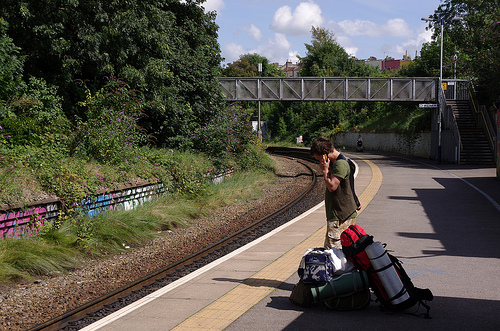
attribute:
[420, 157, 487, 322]
walkway — gray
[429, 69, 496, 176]
stairs — metal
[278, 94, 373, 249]
man — talking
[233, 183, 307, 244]
track — railroad, metal, train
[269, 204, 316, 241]
curb — white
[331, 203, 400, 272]
luggage — red, white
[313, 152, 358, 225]
shirt — green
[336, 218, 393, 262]
backpack — red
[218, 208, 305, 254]
line — white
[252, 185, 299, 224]
railroad — top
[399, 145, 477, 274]
pavement — light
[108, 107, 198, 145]
leave — green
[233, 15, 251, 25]
sky — blue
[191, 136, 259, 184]
grass — green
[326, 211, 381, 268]
suitcase — red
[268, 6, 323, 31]
cloud — white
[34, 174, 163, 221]
wall — colored